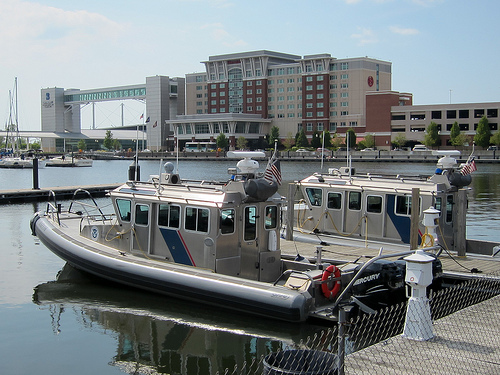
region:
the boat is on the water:
[2, 154, 421, 332]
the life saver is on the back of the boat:
[302, 247, 359, 308]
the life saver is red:
[305, 244, 353, 309]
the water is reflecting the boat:
[21, 262, 289, 366]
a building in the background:
[173, 37, 405, 153]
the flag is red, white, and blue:
[242, 141, 297, 188]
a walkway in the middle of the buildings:
[45, 68, 169, 106]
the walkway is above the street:
[62, 68, 162, 122]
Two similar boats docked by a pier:
[26, 132, 497, 320]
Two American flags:
[261, 154, 480, 187]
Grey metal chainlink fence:
[202, 269, 499, 373]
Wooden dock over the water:
[281, 234, 498, 374]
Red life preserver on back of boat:
[320, 263, 343, 300]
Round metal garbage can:
[261, 346, 342, 374]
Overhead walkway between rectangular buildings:
[40, 75, 187, 152]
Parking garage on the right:
[393, 101, 499, 143]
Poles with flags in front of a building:
[139, 110, 161, 155]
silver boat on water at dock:
[28, 145, 453, 326]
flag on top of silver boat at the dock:
[255, 135, 290, 195]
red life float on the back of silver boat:
[312, 254, 352, 303]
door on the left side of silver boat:
[126, 190, 162, 267]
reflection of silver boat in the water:
[22, 256, 352, 373]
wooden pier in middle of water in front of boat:
[2, 178, 129, 206]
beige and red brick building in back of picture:
[168, 45, 414, 143]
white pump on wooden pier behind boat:
[397, 243, 452, 348]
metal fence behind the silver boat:
[211, 267, 498, 372]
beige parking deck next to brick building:
[384, 98, 499, 149]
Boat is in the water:
[16, 133, 437, 320]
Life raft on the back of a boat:
[315, 257, 343, 299]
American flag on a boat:
[255, 136, 288, 185]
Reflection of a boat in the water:
[23, 263, 248, 367]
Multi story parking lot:
[388, 100, 498, 152]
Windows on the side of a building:
[298, 76, 337, 105]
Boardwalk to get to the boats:
[307, 239, 499, 271]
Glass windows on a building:
[90, 88, 149, 98]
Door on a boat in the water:
[125, 197, 160, 259]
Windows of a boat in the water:
[156, 199, 184, 231]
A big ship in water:
[31, 168, 307, 332]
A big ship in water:
[292, 142, 497, 253]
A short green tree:
[470, 103, 490, 153]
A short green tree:
[442, 120, 463, 149]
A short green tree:
[415, 117, 440, 149]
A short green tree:
[331, 115, 358, 148]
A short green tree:
[293, 118, 311, 149]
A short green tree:
[265, 120, 287, 149]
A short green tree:
[206, 118, 232, 151]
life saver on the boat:
[320, 255, 341, 297]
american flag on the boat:
[261, 140, 301, 190]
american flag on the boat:
[450, 145, 477, 179]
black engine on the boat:
[366, 255, 489, 313]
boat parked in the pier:
[20, 134, 392, 335]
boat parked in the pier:
[236, 133, 498, 265]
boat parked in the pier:
[43, 143, 95, 175]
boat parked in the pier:
[0, 140, 52, 181]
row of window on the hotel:
[336, 63, 351, 130]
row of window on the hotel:
[245, 62, 257, 122]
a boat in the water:
[88, 136, 296, 368]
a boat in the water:
[288, 113, 498, 358]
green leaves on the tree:
[450, 115, 461, 133]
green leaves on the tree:
[427, 116, 439, 141]